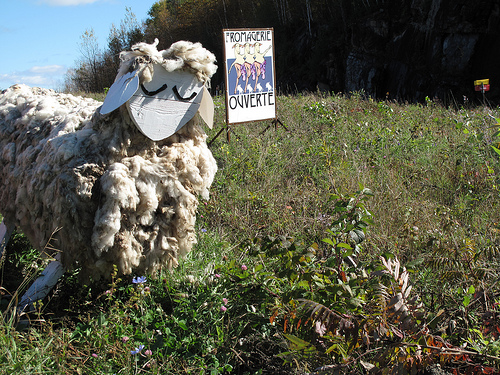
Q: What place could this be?
A: It is a field.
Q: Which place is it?
A: It is a field.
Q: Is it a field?
A: Yes, it is a field.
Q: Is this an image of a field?
A: Yes, it is showing a field.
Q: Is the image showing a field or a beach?
A: It is showing a field.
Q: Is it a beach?
A: No, it is a field.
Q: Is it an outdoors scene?
A: Yes, it is outdoors.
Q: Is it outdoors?
A: Yes, it is outdoors.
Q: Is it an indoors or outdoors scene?
A: It is outdoors.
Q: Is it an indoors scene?
A: No, it is outdoors.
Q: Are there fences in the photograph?
A: No, there are no fences.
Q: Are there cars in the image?
A: No, there are no cars.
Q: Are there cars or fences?
A: No, there are no cars or fences.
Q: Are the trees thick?
A: Yes, the trees are thick.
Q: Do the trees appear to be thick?
A: Yes, the trees are thick.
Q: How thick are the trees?
A: The trees are thick.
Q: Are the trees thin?
A: No, the trees are thick.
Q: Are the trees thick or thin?
A: The trees are thick.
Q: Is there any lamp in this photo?
A: No, there are no lamps.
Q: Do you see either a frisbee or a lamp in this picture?
A: No, there are no lamps or frisbees.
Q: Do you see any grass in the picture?
A: Yes, there is grass.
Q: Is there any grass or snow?
A: Yes, there is grass.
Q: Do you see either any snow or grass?
A: Yes, there is grass.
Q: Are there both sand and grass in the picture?
A: No, there is grass but no sand.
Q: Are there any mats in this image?
A: No, there are no mats.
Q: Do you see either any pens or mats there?
A: No, there are no mats or pens.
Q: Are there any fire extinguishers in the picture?
A: No, there are no fire extinguishers.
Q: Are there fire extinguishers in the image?
A: No, there are no fire extinguishers.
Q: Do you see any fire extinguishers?
A: No, there are no fire extinguishers.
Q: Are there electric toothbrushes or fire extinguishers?
A: No, there are no fire extinguishers or electric toothbrushes.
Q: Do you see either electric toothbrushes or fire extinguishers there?
A: No, there are no fire extinguishers or electric toothbrushes.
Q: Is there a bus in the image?
A: No, there are no buses.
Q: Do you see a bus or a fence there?
A: No, there are no buses or fences.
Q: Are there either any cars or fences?
A: No, there are no cars or fences.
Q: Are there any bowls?
A: No, there are no bowls.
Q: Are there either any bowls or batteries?
A: No, there are no bowls or batteries.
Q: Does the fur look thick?
A: Yes, the fur is thick.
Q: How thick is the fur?
A: The fur is thick.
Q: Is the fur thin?
A: No, the fur is thick.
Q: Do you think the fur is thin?
A: No, the fur is thick.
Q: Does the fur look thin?
A: No, the fur is thick.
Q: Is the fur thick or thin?
A: The fur is thick.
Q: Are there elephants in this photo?
A: No, there are no elephants.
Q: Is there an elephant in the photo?
A: No, there are no elephants.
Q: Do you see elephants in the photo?
A: No, there are no elephants.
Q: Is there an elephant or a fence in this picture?
A: No, there are no elephants or fences.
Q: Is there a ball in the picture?
A: No, there are no balls.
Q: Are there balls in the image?
A: No, there are no balls.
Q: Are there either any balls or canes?
A: No, there are no balls or canes.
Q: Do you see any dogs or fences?
A: No, there are no fences or dogs.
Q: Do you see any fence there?
A: No, there are no fences.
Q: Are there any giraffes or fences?
A: No, there are no fences or giraffes.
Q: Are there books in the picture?
A: No, there are no books.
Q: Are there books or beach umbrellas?
A: No, there are no books or beach umbrellas.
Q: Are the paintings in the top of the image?
A: Yes, the paintings are in the top of the image.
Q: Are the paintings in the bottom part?
A: No, the paintings are in the top of the image.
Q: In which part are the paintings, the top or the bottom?
A: The paintings are in the top of the image.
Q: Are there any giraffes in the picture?
A: No, there are no giraffes.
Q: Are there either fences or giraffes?
A: No, there are no giraffes or fences.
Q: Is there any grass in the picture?
A: Yes, there is grass.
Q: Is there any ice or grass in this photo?
A: Yes, there is grass.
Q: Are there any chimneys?
A: No, there are no chimneys.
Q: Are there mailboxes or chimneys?
A: No, there are no chimneys or mailboxes.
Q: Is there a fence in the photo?
A: No, there are no fences.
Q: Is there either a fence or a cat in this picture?
A: No, there are no fences or cats.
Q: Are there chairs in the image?
A: No, there are no chairs.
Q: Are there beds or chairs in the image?
A: No, there are no chairs or beds.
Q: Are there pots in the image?
A: No, there are no pots.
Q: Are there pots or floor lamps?
A: No, there are no pots or floor lamps.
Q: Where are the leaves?
A: The leaves are on the floor.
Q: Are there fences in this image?
A: No, there are no fences.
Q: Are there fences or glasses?
A: No, there are no fences or glasses.